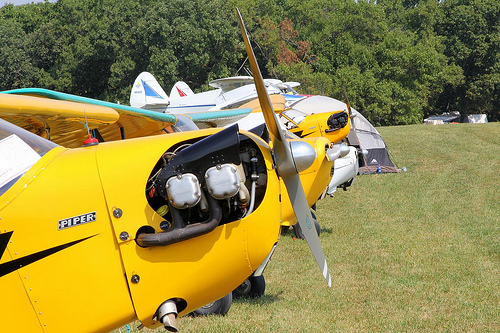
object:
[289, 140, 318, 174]
nose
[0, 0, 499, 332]
picture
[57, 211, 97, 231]
logo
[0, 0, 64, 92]
trees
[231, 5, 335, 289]
propeller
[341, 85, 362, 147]
propeller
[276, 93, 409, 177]
tent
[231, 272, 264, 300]
wheel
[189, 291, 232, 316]
wheel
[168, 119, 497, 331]
grass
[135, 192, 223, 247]
tubing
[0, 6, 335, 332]
airplane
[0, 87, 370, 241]
airplane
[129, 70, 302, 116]
airplane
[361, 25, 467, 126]
trees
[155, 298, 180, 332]
pipe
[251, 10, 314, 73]
tree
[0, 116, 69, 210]
window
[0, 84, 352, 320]
plane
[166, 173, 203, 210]
box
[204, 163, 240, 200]
box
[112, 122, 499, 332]
field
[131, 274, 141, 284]
screw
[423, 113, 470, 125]
buildings